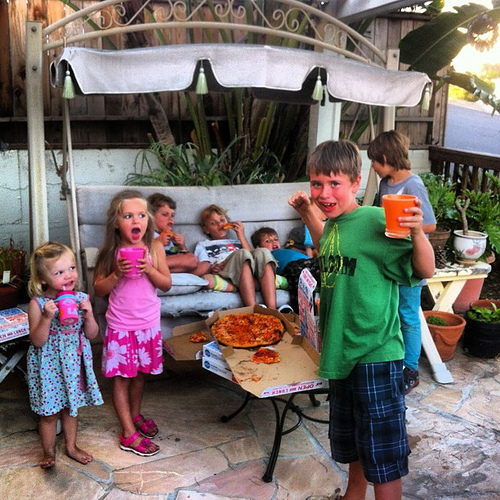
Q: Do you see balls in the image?
A: No, there are no balls.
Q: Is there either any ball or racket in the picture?
A: No, there are no balls or rackets.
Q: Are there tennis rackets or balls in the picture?
A: No, there are no balls or tennis rackets.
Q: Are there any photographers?
A: No, there are no photographers.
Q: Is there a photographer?
A: No, there are no photographers.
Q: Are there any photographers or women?
A: No, there are no photographers or women.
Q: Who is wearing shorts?
A: The boy is wearing shorts.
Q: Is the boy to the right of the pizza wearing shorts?
A: Yes, the boy is wearing shorts.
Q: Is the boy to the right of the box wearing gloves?
A: No, the boy is wearing shorts.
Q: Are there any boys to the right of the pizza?
A: Yes, there is a boy to the right of the pizza.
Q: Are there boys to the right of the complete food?
A: Yes, there is a boy to the right of the pizza.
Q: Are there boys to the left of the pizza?
A: No, the boy is to the right of the pizza.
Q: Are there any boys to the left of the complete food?
A: No, the boy is to the right of the pizza.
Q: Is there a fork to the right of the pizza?
A: No, there is a boy to the right of the pizza.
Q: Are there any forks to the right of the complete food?
A: No, there is a boy to the right of the pizza.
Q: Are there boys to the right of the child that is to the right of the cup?
A: Yes, there is a boy to the right of the child.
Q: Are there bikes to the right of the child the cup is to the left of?
A: No, there is a boy to the right of the kid.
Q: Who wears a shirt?
A: The boy wears a shirt.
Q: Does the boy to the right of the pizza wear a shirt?
A: Yes, the boy wears a shirt.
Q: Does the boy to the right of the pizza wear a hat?
A: No, the boy wears a shirt.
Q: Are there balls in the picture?
A: No, there are no balls.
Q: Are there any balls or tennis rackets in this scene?
A: No, there are no balls or tennis rackets.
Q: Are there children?
A: Yes, there is a child.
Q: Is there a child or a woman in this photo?
A: Yes, there is a child.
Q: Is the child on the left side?
A: Yes, the child is on the left of the image.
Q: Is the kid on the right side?
A: No, the kid is on the left of the image.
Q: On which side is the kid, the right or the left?
A: The kid is on the left of the image.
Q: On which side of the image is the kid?
A: The kid is on the left of the image.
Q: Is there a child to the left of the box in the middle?
A: Yes, there is a child to the left of the box.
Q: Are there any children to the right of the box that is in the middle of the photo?
A: No, the child is to the left of the box.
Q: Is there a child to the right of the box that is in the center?
A: No, the child is to the left of the box.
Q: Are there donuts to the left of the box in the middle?
A: No, there is a child to the left of the box.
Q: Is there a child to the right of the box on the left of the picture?
A: Yes, there is a child to the right of the box.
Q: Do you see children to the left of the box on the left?
A: No, the child is to the right of the box.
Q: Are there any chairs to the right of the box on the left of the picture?
A: No, there is a child to the right of the box.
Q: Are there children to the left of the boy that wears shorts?
A: Yes, there is a child to the left of the boy.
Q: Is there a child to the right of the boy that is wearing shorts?
A: No, the child is to the left of the boy.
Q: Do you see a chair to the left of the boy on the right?
A: No, there is a child to the left of the boy.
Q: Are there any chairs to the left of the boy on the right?
A: No, there is a child to the left of the boy.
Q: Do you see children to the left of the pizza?
A: Yes, there is a child to the left of the pizza.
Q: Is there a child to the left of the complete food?
A: Yes, there is a child to the left of the pizza.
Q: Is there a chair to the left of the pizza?
A: No, there is a child to the left of the pizza.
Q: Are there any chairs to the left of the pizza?
A: No, there is a child to the left of the pizza.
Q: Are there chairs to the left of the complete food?
A: No, there is a child to the left of the pizza.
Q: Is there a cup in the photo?
A: Yes, there is a cup.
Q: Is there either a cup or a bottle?
A: Yes, there is a cup.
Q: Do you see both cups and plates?
A: No, there is a cup but no plates.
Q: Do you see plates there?
A: No, there are no plates.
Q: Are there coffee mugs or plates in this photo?
A: No, there are no plates or coffee mugs.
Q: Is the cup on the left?
A: Yes, the cup is on the left of the image.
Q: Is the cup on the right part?
A: No, the cup is on the left of the image.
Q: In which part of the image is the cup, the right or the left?
A: The cup is on the left of the image.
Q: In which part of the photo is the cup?
A: The cup is on the left of the image.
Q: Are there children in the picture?
A: Yes, there is a child.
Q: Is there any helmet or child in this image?
A: Yes, there is a child.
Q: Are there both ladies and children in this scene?
A: No, there is a child but no ladies.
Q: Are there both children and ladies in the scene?
A: No, there is a child but no ladies.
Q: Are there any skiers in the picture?
A: No, there are no skiers.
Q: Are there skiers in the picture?
A: No, there are no skiers.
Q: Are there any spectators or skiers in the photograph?
A: No, there are no skiers or spectators.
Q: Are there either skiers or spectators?
A: No, there are no skiers or spectators.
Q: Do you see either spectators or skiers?
A: No, there are no skiers or spectators.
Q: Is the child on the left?
A: Yes, the child is on the left of the image.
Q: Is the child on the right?
A: No, the child is on the left of the image.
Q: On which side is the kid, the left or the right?
A: The kid is on the left of the image.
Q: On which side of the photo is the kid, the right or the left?
A: The kid is on the left of the image.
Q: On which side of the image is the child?
A: The child is on the left of the image.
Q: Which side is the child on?
A: The child is on the left of the image.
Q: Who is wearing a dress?
A: The child is wearing a dress.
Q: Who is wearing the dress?
A: The child is wearing a dress.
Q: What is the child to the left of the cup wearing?
A: The child is wearing a dress.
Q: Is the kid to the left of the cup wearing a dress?
A: Yes, the child is wearing a dress.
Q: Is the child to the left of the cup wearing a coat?
A: No, the child is wearing a dress.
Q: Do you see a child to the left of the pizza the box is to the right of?
A: Yes, there is a child to the left of the pizza.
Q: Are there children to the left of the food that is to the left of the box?
A: Yes, there is a child to the left of the pizza.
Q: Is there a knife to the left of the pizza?
A: No, there is a child to the left of the pizza.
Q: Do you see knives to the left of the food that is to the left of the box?
A: No, there is a child to the left of the pizza.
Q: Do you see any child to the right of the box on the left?
A: Yes, there is a child to the right of the box.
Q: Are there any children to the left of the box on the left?
A: No, the child is to the right of the box.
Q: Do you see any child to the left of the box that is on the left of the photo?
A: No, the child is to the right of the box.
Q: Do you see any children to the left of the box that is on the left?
A: No, the child is to the right of the box.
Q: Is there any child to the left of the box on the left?
A: No, the child is to the right of the box.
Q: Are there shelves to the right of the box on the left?
A: No, there is a child to the right of the box.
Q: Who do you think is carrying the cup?
A: The kid is carrying the cup.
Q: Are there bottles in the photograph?
A: No, there are no bottles.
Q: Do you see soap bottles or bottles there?
A: No, there are no bottles or soap bottles.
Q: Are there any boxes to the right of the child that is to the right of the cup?
A: Yes, there is a box to the right of the kid.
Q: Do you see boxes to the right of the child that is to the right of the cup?
A: Yes, there is a box to the right of the kid.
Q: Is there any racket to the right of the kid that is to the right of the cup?
A: No, there is a box to the right of the child.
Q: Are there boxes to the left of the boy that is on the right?
A: Yes, there is a box to the left of the boy.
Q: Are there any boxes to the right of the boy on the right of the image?
A: No, the box is to the left of the boy.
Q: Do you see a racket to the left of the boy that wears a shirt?
A: No, there is a box to the left of the boy.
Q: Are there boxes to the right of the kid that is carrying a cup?
A: Yes, there is a box to the right of the child.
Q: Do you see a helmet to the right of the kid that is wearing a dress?
A: No, there is a box to the right of the child.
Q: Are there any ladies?
A: No, there are no ladies.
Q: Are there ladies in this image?
A: No, there are no ladies.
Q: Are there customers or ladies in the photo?
A: No, there are no ladies or customers.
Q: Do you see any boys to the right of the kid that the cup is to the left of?
A: Yes, there is a boy to the right of the kid.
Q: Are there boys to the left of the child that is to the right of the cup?
A: No, the boy is to the right of the kid.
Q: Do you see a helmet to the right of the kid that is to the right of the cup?
A: No, there is a boy to the right of the kid.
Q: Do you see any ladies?
A: No, there are no ladies.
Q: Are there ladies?
A: No, there are no ladies.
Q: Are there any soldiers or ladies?
A: No, there are no ladies or soldiers.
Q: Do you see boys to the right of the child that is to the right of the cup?
A: Yes, there is a boy to the right of the child.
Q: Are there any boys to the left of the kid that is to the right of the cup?
A: No, the boy is to the right of the child.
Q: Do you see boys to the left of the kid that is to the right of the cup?
A: No, the boy is to the right of the child.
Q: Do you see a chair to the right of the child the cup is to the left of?
A: No, there is a boy to the right of the kid.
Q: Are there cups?
A: Yes, there is a cup.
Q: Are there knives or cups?
A: Yes, there is a cup.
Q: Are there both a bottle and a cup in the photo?
A: No, there is a cup but no bottles.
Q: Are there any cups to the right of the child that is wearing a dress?
A: Yes, there is a cup to the right of the kid.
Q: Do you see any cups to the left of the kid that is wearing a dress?
A: No, the cup is to the right of the child.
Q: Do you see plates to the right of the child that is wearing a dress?
A: No, there is a cup to the right of the child.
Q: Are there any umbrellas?
A: No, there are no umbrellas.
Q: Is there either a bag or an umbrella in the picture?
A: No, there are no umbrellas or bags.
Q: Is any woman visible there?
A: No, there are no women.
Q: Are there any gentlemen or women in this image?
A: No, there are no women or gentlemen.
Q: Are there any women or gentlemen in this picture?
A: No, there are no women or gentlemen.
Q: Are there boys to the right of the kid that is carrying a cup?
A: Yes, there is a boy to the right of the child.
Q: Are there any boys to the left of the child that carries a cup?
A: No, the boy is to the right of the child.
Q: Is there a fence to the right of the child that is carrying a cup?
A: No, there is a boy to the right of the kid.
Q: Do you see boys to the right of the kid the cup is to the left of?
A: Yes, there is a boy to the right of the kid.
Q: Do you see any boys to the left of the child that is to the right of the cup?
A: No, the boy is to the right of the kid.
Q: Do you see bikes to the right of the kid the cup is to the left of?
A: No, there is a boy to the right of the kid.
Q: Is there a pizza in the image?
A: Yes, there is a pizza.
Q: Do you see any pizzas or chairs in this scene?
A: Yes, there is a pizza.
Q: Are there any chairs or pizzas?
A: Yes, there is a pizza.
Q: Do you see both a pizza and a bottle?
A: No, there is a pizza but no bottles.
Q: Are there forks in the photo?
A: No, there are no forks.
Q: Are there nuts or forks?
A: No, there are no forks or nuts.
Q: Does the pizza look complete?
A: Yes, the pizza is complete.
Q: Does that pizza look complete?
A: Yes, the pizza is complete.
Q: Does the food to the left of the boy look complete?
A: Yes, the pizza is complete.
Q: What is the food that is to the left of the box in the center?
A: The food is a pizza.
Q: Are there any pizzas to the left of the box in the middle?
A: Yes, there is a pizza to the left of the box.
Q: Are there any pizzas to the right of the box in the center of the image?
A: No, the pizza is to the left of the box.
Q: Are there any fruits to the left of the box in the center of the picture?
A: No, there is a pizza to the left of the box.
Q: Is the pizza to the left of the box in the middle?
A: Yes, the pizza is to the left of the box.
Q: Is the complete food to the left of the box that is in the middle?
A: Yes, the pizza is to the left of the box.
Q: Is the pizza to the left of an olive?
A: No, the pizza is to the left of the box.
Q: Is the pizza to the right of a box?
A: No, the pizza is to the left of a box.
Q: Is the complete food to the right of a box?
A: No, the pizza is to the left of a box.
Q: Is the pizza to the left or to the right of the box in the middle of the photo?
A: The pizza is to the left of the box.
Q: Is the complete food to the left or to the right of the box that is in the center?
A: The pizza is to the left of the box.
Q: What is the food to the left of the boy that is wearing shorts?
A: The food is a pizza.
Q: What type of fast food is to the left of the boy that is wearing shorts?
A: The food is a pizza.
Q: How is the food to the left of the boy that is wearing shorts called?
A: The food is a pizza.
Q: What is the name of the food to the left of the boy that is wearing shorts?
A: The food is a pizza.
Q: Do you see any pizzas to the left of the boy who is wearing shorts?
A: Yes, there is a pizza to the left of the boy.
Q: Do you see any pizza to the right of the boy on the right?
A: No, the pizza is to the left of the boy.